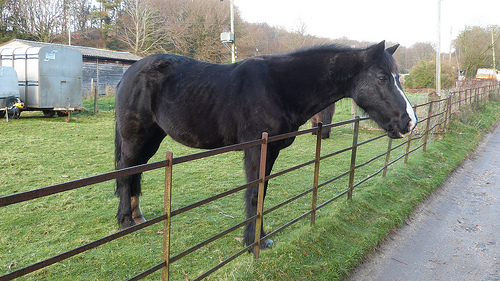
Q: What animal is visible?
A: Horse.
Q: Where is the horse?
A: In a fenced field.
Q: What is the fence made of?
A: Metal.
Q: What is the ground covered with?
A: Grass.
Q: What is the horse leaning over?
A: Fence.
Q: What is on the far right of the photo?
A: Road.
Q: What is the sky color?
A: Gray.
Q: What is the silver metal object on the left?
A: Trailer.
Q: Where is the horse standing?
A: Outside in the field.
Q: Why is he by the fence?
A: He's looking for food.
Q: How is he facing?
A: Towards the road.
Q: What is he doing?
A: Standing with his head over the fence.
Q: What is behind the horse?
A: A silver trailer.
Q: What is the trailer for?
A: Transporting the horse.